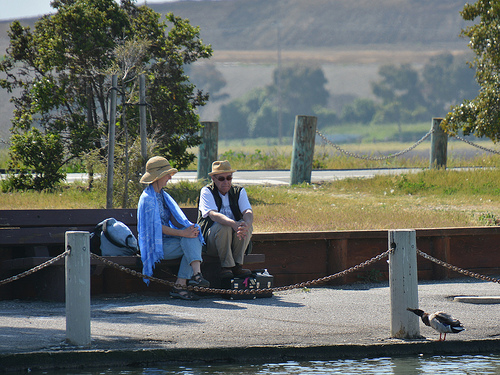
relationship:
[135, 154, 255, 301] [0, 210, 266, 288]
couple sitting on bench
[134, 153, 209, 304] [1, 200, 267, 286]
woman sitting on bench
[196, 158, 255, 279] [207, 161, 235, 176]
man wearing hat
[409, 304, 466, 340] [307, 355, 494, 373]
bird standing beside water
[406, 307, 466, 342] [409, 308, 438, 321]
bird stretching its neck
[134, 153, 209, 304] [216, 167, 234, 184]
woman wearing glasses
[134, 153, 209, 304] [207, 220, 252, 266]
woman wearing pants